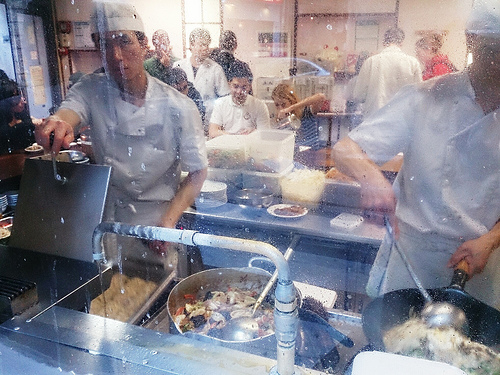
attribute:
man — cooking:
[34, 2, 208, 273]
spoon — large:
[384, 217, 470, 341]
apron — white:
[106, 200, 189, 281]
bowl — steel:
[232, 188, 277, 216]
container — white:
[244, 129, 297, 175]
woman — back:
[269, 83, 328, 148]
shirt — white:
[56, 66, 210, 203]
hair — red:
[270, 81, 303, 124]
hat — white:
[90, 1, 146, 35]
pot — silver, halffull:
[166, 266, 303, 361]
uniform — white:
[57, 63, 208, 268]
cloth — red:
[422, 54, 456, 80]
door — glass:
[14, 13, 57, 118]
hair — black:
[226, 60, 253, 86]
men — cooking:
[35, 2, 499, 310]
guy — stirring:
[333, 0, 498, 310]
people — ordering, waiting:
[143, 30, 325, 150]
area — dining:
[0, 47, 499, 182]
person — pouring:
[271, 82, 325, 147]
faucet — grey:
[91, 222, 300, 373]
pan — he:
[363, 260, 499, 373]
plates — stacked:
[192, 181, 229, 211]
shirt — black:
[210, 54, 253, 94]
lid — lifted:
[11, 158, 113, 265]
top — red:
[422, 53, 457, 82]